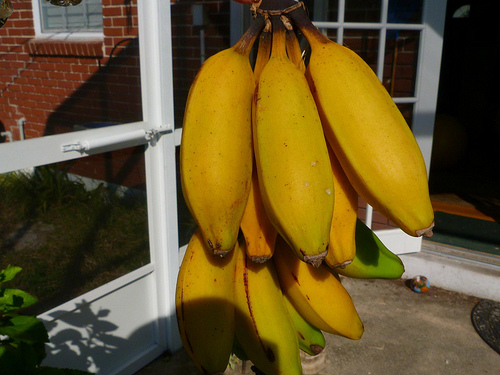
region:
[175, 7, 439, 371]
bunch of yellow fruit, possibly papayas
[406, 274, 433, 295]
a colorful tidbit laying on the ground outside the doorway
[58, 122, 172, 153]
white door spring mechanism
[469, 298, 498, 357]
partial half circle type rug mostly gray in color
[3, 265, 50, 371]
partial green leafy plant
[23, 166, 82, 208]
large tuft of green grass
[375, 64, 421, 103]
single window in a multipaned door above and behind the papayas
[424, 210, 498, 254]
rectangular green rug inside the door on a wooden floor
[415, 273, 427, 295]
The ball on the ground.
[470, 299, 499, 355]
The mat in front of the door.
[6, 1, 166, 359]
The screen door of the patio.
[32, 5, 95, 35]
The window of the house.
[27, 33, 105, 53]
The brick windowsill of the window.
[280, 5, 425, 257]
The open door of the house.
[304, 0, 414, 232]
The panel windows on the door.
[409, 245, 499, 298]
The step in front of the door.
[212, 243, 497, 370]
The cement area of the patio.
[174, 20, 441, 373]
The hanging bananas.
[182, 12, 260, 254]
a large yellow banana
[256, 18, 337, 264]
a large yellow banana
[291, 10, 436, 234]
a large yellow banana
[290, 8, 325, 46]
brown stem of a banana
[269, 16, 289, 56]
brown stem of a banana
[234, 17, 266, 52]
brown stem of a banana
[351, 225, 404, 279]
green tip of a banana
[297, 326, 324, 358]
green tip of a banana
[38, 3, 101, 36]
window on a brick home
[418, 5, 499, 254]
an open door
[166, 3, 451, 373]
A held up banana stalk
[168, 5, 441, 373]
A held up banana stalk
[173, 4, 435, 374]
A held up banana stalk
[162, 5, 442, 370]
A held up banana stalk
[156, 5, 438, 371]
A held up banana stalk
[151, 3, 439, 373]
A held up banana stalk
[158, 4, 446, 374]
A held up banana stalk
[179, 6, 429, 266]
a bundle of bananas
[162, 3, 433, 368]
the bananas are hanging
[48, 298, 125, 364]
a shadow on the door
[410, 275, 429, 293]
a toy on the ground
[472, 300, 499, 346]
a outdoor rug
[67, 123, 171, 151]
spring on the door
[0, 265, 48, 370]
green leaves on the plant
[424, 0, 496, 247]
the door is open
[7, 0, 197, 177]
a red brick wall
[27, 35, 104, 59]
a brick window case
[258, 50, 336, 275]
A small yellow banana.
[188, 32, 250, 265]
A small yellow banana.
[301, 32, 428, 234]
A small yellow banana.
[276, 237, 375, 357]
A small yellow banana.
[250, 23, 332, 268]
Banana next to a banana